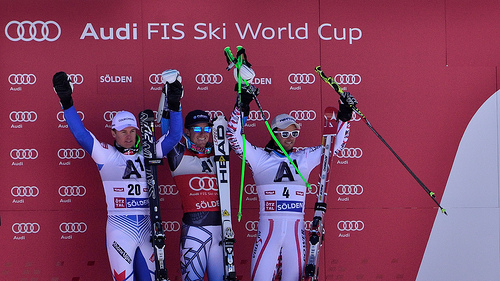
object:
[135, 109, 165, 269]
skis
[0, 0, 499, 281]
wall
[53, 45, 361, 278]
champions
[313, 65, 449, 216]
pole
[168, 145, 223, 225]
top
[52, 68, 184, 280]
man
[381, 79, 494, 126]
blue tent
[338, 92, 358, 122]
glove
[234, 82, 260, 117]
glove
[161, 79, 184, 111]
glove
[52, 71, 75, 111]
gloves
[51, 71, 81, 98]
hand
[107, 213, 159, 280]
pants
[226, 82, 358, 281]
person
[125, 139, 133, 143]
mouth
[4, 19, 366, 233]
rings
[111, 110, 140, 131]
cap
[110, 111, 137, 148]
head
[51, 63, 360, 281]
people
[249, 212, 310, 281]
pants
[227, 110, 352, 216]
top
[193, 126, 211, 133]
shades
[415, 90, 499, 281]
snow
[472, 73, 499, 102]
tent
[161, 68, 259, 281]
man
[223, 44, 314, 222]
poles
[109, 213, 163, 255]
ski sportwear